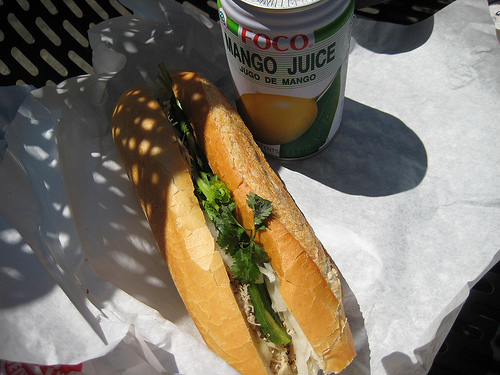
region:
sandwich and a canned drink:
[130, 2, 399, 356]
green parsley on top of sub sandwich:
[220, 193, 272, 286]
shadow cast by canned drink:
[330, 107, 441, 203]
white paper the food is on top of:
[415, 230, 483, 360]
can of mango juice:
[207, 0, 374, 173]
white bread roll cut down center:
[176, 238, 225, 334]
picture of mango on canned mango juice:
[235, 83, 329, 147]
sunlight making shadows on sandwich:
[45, 78, 160, 291]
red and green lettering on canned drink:
[215, 26, 352, 95]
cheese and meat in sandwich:
[251, 276, 314, 368]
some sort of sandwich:
[105, 70, 374, 374]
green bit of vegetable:
[197, 171, 229, 214]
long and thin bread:
[100, 75, 361, 373]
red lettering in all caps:
[240, 22, 313, 54]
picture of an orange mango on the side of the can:
[236, 87, 321, 149]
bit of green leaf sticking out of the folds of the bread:
[247, 189, 272, 233]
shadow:
[3, 16, 183, 319]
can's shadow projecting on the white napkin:
[306, 100, 440, 207]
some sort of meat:
[235, 287, 282, 356]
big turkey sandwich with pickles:
[115, 77, 325, 345]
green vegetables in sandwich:
[162, 156, 289, 281]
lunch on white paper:
[95, 33, 429, 352]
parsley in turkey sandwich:
[207, 199, 284, 275]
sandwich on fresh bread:
[121, 118, 395, 366]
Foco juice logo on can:
[234, 22, 316, 59]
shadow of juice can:
[309, 73, 487, 241]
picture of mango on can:
[244, 83, 333, 145]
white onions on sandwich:
[250, 266, 346, 373]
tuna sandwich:
[113, 70, 355, 373]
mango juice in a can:
[210, 5, 369, 162]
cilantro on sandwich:
[190, 174, 275, 290]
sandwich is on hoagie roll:
[106, 71, 336, 372]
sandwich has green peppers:
[238, 272, 295, 357]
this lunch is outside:
[68, 5, 408, 373]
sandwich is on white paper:
[35, 88, 489, 373]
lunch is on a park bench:
[3, 6, 493, 371]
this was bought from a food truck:
[51, 7, 469, 374]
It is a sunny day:
[55, 13, 461, 373]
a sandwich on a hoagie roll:
[110, 55, 385, 373]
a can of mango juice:
[204, 2, 355, 149]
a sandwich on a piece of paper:
[78, 81, 408, 374]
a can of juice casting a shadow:
[216, 2, 456, 209]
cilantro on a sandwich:
[176, 153, 319, 350]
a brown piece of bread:
[268, 227, 393, 372]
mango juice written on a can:
[222, 16, 346, 88]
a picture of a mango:
[231, 83, 337, 150]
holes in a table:
[11, 15, 121, 95]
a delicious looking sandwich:
[103, 52, 375, 372]